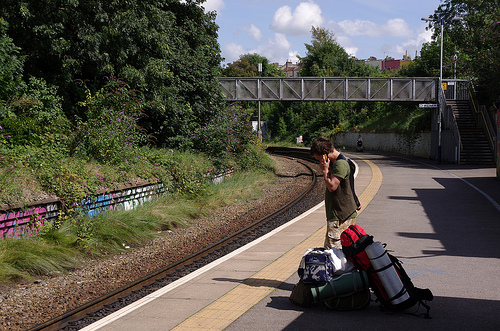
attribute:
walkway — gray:
[420, 157, 487, 322]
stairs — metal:
[429, 69, 496, 176]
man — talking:
[278, 94, 373, 249]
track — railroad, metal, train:
[233, 183, 307, 244]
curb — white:
[269, 204, 316, 241]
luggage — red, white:
[331, 203, 400, 272]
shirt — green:
[313, 152, 358, 225]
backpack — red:
[336, 218, 393, 262]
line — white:
[218, 208, 305, 254]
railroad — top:
[252, 185, 299, 224]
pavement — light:
[399, 145, 477, 274]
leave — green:
[108, 107, 198, 145]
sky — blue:
[233, 15, 251, 25]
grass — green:
[191, 136, 259, 184]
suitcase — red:
[326, 211, 381, 268]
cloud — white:
[268, 6, 323, 31]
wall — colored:
[34, 174, 163, 221]